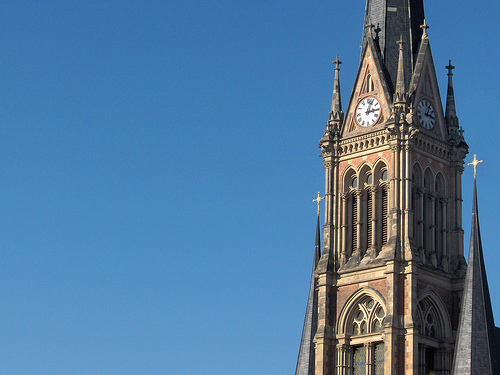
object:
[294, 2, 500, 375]
tower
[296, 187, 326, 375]
spires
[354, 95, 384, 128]
clock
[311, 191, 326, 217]
crosses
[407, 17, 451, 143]
spires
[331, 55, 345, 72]
crosses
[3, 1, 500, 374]
sky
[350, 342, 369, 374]
windows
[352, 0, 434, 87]
steeple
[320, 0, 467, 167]
tops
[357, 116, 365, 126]
numbers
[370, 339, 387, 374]
window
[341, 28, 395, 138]
panel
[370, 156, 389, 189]
arches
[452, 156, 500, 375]
spire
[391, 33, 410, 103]
spire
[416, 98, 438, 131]
clock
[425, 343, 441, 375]
window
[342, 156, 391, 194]
third window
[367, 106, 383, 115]
hands